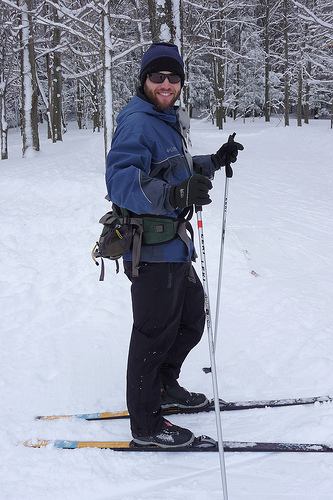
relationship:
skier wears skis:
[93, 41, 243, 455] [199, 128, 235, 446]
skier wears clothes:
[93, 41, 243, 455] [92, 86, 246, 436]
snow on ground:
[7, 162, 125, 407] [9, 160, 97, 401]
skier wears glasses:
[93, 41, 243, 455] [146, 71, 182, 86]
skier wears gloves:
[93, 41, 243, 455] [168, 140, 259, 209]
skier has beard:
[93, 41, 243, 455] [145, 86, 181, 109]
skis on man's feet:
[199, 128, 235, 446] [128, 383, 210, 447]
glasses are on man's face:
[146, 72, 182, 83] [144, 69, 184, 107]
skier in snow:
[93, 41, 243, 455] [7, 162, 125, 407]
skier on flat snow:
[26, 41, 332, 454] [7, 162, 125, 407]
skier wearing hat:
[26, 41, 332, 454] [134, 43, 188, 87]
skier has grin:
[26, 41, 332, 454] [157, 91, 173, 97]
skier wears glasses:
[26, 41, 332, 454] [146, 72, 182, 83]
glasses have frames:
[146, 72, 182, 83] [151, 71, 179, 78]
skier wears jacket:
[26, 41, 332, 454] [105, 93, 216, 258]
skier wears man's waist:
[26, 41, 332, 454] [112, 195, 184, 259]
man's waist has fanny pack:
[112, 195, 184, 259] [143, 216, 175, 244]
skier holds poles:
[26, 41, 332, 454] [176, 157, 231, 499]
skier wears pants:
[26, 41, 332, 454] [127, 263, 205, 439]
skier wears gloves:
[26, 41, 332, 454] [168, 140, 259, 209]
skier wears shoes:
[26, 41, 332, 454] [128, 383, 210, 447]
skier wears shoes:
[93, 41, 243, 455] [128, 383, 210, 447]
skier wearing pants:
[93, 41, 243, 455] [127, 263, 205, 439]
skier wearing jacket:
[93, 41, 243, 455] [105, 93, 216, 258]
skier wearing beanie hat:
[93, 41, 243, 455] [134, 43, 188, 87]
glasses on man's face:
[146, 72, 182, 83] [144, 69, 184, 107]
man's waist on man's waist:
[112, 195, 184, 259] [112, 195, 196, 264]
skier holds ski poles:
[93, 41, 243, 455] [199, 128, 235, 446]